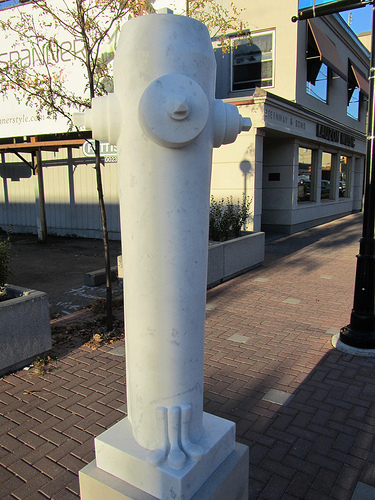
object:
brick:
[262, 385, 295, 408]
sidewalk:
[1, 214, 372, 497]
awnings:
[349, 62, 371, 103]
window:
[230, 32, 273, 91]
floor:
[0, 208, 375, 500]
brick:
[259, 385, 291, 409]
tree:
[0, 0, 157, 331]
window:
[345, 59, 371, 122]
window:
[294, 142, 322, 208]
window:
[319, 147, 340, 205]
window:
[338, 155, 349, 201]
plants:
[206, 190, 255, 240]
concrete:
[206, 232, 268, 288]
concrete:
[0, 293, 49, 367]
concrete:
[210, 126, 262, 230]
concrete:
[69, 5, 253, 497]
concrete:
[330, 333, 375, 359]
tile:
[200, 224, 372, 496]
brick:
[45, 425, 67, 447]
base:
[80, 413, 250, 500]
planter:
[0, 271, 54, 378]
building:
[0, 3, 374, 237]